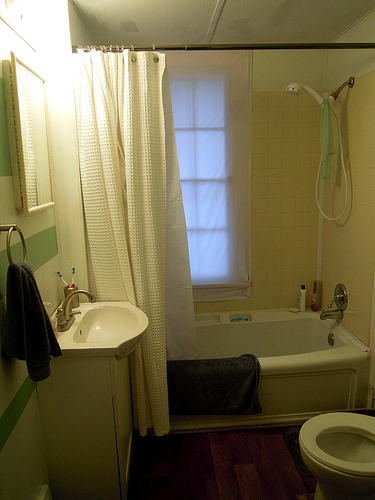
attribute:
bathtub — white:
[170, 306, 370, 428]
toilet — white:
[298, 410, 374, 497]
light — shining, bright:
[7, 3, 88, 109]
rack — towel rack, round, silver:
[4, 223, 36, 274]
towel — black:
[9, 261, 78, 367]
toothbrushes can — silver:
[55, 266, 80, 308]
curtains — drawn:
[173, 59, 248, 293]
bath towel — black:
[166, 353, 263, 416]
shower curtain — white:
[71, 39, 198, 435]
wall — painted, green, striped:
[5, 1, 73, 499]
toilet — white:
[290, 396, 369, 493]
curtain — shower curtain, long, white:
[70, 49, 235, 435]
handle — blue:
[228, 312, 244, 324]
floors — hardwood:
[155, 426, 277, 496]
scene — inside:
[6, 26, 374, 469]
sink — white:
[45, 297, 151, 359]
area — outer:
[238, 303, 310, 321]